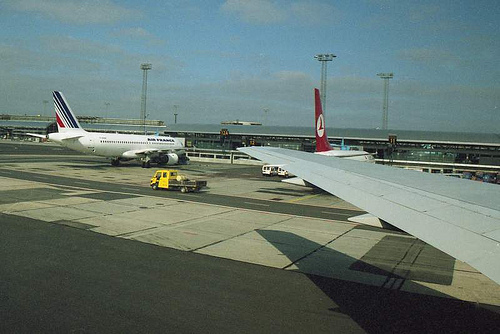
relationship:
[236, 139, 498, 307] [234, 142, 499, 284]
wing of plane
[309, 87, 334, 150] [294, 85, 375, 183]
wing of plane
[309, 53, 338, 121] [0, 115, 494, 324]
tower of airport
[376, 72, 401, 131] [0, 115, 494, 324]
tower of airport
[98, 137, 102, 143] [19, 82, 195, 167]
window of aircraft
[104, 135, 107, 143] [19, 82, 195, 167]
window of aircraft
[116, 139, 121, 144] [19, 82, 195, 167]
window of aircraft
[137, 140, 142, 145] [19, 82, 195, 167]
window of aircraft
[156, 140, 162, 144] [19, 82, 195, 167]
window of aircraft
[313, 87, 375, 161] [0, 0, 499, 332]
airplane at airport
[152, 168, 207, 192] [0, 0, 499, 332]
luggage truck on airport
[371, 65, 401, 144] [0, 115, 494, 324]
tower on an airport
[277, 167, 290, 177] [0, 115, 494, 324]
car at airport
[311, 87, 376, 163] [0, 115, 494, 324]
airplane at airport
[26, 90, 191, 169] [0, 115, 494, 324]
airplane at airport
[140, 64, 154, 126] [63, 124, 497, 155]
airplane towers on roof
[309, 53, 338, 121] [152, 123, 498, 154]
tower on roof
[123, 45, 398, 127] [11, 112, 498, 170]
airplane towers on roof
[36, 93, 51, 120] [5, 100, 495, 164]
airplane tower on roof